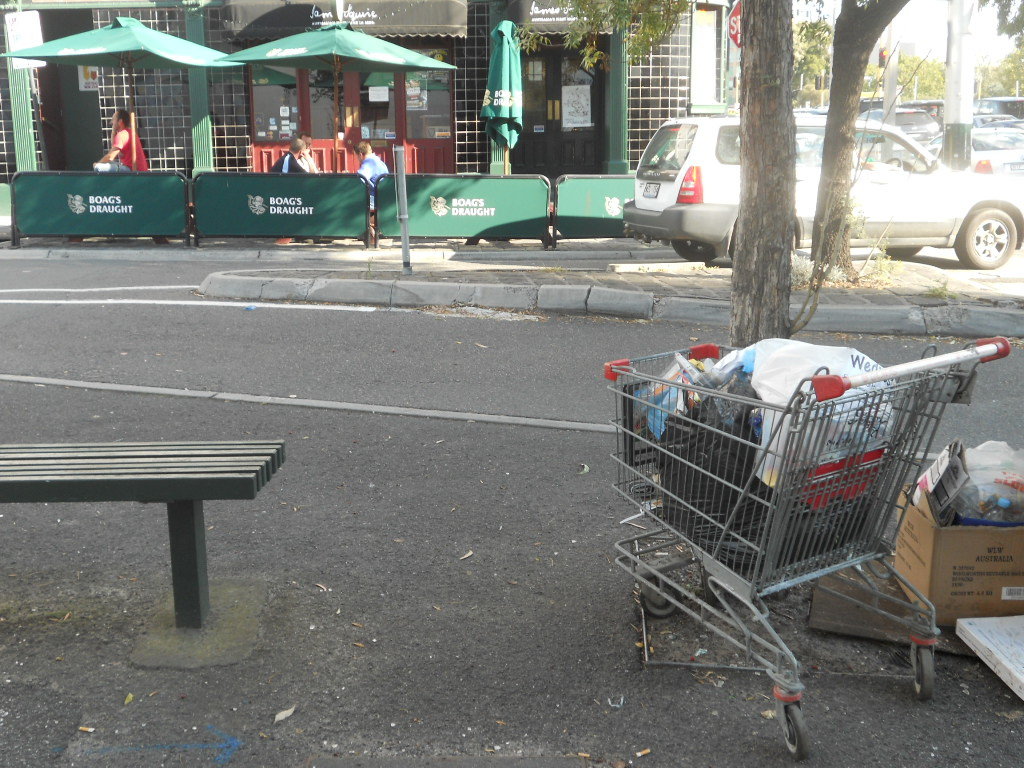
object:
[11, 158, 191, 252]
barricade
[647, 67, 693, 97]
window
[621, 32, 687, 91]
window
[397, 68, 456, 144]
window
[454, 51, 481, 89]
window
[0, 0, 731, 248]
building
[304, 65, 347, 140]
window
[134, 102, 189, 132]
window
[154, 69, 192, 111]
window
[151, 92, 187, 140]
window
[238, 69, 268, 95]
window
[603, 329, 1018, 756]
shopping cart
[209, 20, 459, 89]
umbrella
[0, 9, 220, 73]
umbrella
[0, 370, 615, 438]
line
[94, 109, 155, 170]
man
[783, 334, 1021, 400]
handle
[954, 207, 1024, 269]
wheel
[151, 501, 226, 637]
bench leg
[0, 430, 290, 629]
bench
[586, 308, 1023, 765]
cart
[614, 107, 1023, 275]
automobile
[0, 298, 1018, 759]
street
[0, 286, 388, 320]
lines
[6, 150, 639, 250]
green barrier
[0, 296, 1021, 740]
road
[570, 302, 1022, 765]
cart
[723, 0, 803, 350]
tree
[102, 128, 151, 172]
shirt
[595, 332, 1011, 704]
shopping cart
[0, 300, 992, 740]
pavement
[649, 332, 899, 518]
merchandise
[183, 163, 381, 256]
barricade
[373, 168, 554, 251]
barricade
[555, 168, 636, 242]
barricade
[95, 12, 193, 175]
window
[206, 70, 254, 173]
window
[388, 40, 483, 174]
window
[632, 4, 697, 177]
window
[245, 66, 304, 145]
window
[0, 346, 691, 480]
view